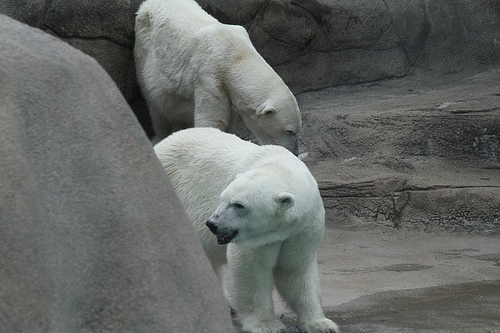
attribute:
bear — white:
[152, 119, 352, 330]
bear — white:
[144, 123, 330, 329]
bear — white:
[136, 3, 312, 157]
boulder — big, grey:
[2, 15, 235, 329]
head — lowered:
[250, 89, 307, 162]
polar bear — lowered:
[127, 2, 311, 161]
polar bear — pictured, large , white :
[148, 119, 337, 330]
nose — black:
[201, 215, 220, 233]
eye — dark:
[226, 199, 248, 212]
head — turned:
[203, 166, 278, 254]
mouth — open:
[207, 217, 244, 246]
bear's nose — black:
[204, 218, 224, 235]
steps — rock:
[298, 71, 498, 228]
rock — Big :
[0, 11, 242, 330]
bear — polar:
[169, 114, 353, 307]